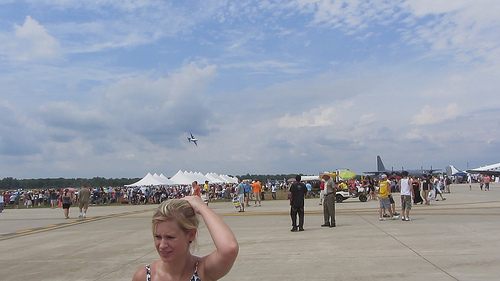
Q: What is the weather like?
A: It is cloudy.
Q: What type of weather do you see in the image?
A: It is cloudy.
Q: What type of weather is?
A: It is cloudy.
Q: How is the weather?
A: It is cloudy.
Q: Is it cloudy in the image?
A: Yes, it is cloudy.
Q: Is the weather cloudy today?
A: Yes, it is cloudy.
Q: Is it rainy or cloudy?
A: It is cloudy.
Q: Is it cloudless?
A: No, it is cloudy.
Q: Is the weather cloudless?
A: No, it is cloudy.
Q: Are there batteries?
A: No, there are no batteries.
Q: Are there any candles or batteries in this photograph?
A: No, there are no batteries or candles.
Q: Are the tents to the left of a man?
A: Yes, the tents are to the left of a man.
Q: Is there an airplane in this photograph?
A: Yes, there is an airplane.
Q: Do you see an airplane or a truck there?
A: Yes, there is an airplane.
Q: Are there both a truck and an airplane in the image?
A: No, there is an airplane but no trucks.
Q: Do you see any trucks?
A: No, there are no trucks.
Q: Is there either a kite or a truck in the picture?
A: No, there are no trucks or kites.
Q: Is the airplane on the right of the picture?
A: Yes, the airplane is on the right of the image.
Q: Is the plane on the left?
A: No, the plane is on the right of the image.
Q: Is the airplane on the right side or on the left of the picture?
A: The airplane is on the right of the image.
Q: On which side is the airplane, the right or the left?
A: The airplane is on the right of the image.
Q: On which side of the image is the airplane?
A: The airplane is on the right of the image.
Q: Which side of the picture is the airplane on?
A: The airplane is on the right of the image.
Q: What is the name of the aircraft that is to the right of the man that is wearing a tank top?
A: The aircraft is an airplane.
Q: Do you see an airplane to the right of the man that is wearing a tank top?
A: Yes, there is an airplane to the right of the man.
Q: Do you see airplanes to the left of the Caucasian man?
A: No, the airplane is to the right of the man.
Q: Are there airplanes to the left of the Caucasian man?
A: No, the airplane is to the right of the man.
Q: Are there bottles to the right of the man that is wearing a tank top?
A: No, there is an airplane to the right of the man.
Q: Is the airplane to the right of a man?
A: Yes, the airplane is to the right of a man.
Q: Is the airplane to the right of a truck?
A: No, the airplane is to the right of a man.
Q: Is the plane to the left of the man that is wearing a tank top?
A: No, the plane is to the right of the man.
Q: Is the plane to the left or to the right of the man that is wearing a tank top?
A: The plane is to the right of the man.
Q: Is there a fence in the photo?
A: No, there are no fences.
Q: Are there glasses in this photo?
A: No, there are no glasses.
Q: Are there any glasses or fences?
A: No, there are no glasses or fences.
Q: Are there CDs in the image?
A: No, there are no cds.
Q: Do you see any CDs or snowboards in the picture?
A: No, there are no CDs or snowboards.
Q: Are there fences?
A: No, there are no fences.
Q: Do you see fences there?
A: No, there are no fences.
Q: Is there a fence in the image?
A: No, there are no fences.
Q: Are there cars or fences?
A: No, there are no fences or cars.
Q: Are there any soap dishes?
A: No, there are no soap dishes.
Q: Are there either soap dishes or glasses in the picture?
A: No, there are no soap dishes or glasses.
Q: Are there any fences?
A: No, there are no fences.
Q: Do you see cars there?
A: No, there are no cars.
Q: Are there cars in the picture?
A: No, there are no cars.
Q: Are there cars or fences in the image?
A: No, there are no cars or fences.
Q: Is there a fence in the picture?
A: No, there are no fences.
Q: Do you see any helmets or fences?
A: No, there are no fences or helmets.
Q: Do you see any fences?
A: No, there are no fences.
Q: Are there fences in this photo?
A: No, there are no fences.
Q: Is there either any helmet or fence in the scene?
A: No, there are no fences or helmets.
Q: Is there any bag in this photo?
A: No, there are no bags.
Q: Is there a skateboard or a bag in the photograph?
A: No, there are no bags or skateboards.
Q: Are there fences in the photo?
A: No, there are no fences.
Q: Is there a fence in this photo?
A: No, there are no fences.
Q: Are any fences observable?
A: No, there are no fences.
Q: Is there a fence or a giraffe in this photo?
A: No, there are no fences or giraffes.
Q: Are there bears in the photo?
A: No, there are no bears.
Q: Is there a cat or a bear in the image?
A: No, there are no bears or cats.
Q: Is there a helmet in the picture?
A: No, there are no helmets.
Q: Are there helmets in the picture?
A: No, there are no helmets.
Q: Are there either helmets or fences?
A: No, there are no helmets or fences.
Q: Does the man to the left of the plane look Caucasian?
A: Yes, the man is caucasian.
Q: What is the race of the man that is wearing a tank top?
A: The man is caucasian.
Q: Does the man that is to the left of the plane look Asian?
A: No, the man is caucasian.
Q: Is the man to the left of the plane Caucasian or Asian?
A: The man is caucasian.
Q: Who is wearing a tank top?
A: The man is wearing a tank top.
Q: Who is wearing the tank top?
A: The man is wearing a tank top.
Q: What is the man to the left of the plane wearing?
A: The man is wearing a tank top.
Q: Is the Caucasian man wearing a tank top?
A: Yes, the man is wearing a tank top.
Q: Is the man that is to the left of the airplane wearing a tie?
A: No, the man is wearing a tank top.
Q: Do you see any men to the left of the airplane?
A: Yes, there is a man to the left of the airplane.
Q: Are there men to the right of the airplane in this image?
A: No, the man is to the left of the airplane.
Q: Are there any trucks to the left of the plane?
A: No, there is a man to the left of the plane.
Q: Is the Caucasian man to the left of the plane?
A: Yes, the man is to the left of the plane.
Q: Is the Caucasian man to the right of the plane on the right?
A: No, the man is to the left of the airplane.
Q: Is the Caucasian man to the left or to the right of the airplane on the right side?
A: The man is to the left of the plane.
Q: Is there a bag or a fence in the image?
A: No, there are no fences or bags.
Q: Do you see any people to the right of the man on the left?
A: Yes, there is a person to the right of the man.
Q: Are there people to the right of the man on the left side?
A: Yes, there is a person to the right of the man.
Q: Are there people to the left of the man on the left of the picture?
A: No, the person is to the right of the man.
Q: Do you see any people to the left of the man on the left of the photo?
A: No, the person is to the right of the man.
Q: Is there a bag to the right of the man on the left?
A: No, there is a person to the right of the man.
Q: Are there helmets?
A: No, there are no helmets.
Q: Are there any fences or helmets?
A: No, there are no helmets or fences.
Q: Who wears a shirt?
A: The man wears a shirt.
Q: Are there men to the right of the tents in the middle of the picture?
A: Yes, there is a man to the right of the tents.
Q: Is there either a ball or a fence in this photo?
A: No, there are no fences or balls.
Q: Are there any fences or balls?
A: No, there are no fences or balls.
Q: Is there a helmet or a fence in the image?
A: No, there are no fences or helmets.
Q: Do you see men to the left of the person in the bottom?
A: Yes, there is a man to the left of the person.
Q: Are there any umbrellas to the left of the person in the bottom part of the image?
A: No, there is a man to the left of the person.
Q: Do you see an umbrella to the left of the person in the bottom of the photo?
A: No, there is a man to the left of the person.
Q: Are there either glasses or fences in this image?
A: No, there are no fences or glasses.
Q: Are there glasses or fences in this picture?
A: No, there are no fences or glasses.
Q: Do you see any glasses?
A: No, there are no glasses.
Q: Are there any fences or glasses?
A: No, there are no glasses or fences.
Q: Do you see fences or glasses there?
A: No, there are no glasses or fences.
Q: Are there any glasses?
A: No, there are no glasses.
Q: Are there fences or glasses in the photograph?
A: No, there are no glasses or fences.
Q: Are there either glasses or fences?
A: No, there are no glasses or fences.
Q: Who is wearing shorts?
A: The man is wearing shorts.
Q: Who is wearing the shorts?
A: The man is wearing shorts.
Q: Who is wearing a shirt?
A: The man is wearing a shirt.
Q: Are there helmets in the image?
A: No, there are no helmets.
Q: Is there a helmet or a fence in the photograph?
A: No, there are no helmets or fences.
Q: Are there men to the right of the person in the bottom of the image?
A: Yes, there is a man to the right of the person.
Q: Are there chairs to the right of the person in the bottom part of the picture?
A: No, there is a man to the right of the person.